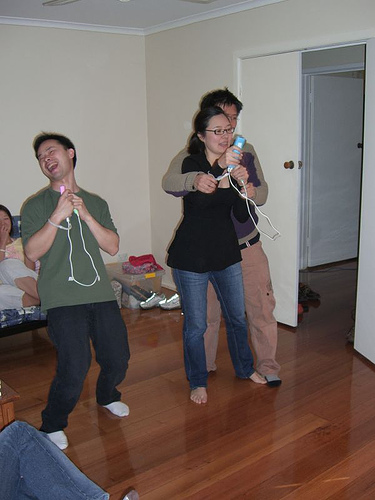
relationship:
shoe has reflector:
[157, 286, 180, 313] [154, 290, 175, 307]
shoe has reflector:
[135, 288, 169, 311] [134, 288, 157, 309]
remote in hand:
[229, 136, 247, 172] [215, 143, 241, 173]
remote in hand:
[229, 136, 247, 172] [230, 163, 250, 185]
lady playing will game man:
[164, 104, 269, 405] [162, 87, 268, 386]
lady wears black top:
[164, 104, 269, 405] [164, 148, 252, 274]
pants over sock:
[38, 300, 130, 433] [101, 401, 129, 417]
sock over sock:
[123, 489, 139, 499] [46, 430, 67, 448]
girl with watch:
[0, 197, 13, 331] [0, 245, 8, 254]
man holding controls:
[19, 133, 131, 449] [217, 129, 247, 179]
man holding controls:
[19, 133, 131, 449] [56, 179, 79, 224]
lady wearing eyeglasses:
[164, 104, 269, 405] [199, 127, 236, 138]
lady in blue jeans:
[164, 104, 269, 405] [168, 261, 261, 386]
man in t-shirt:
[19, 133, 131, 449] [20, 187, 117, 311]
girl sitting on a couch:
[0, 197, 41, 313] [1, 212, 55, 342]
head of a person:
[27, 126, 80, 179] [27, 131, 162, 365]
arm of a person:
[23, 188, 72, 269] [15, 126, 144, 451]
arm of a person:
[19, 188, 73, 265] [15, 126, 144, 451]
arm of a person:
[19, 188, 73, 265] [7, 123, 157, 390]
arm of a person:
[67, 192, 127, 260] [4, 123, 139, 457]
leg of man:
[37, 305, 90, 432] [19, 133, 131, 449]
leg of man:
[83, 301, 132, 408] [19, 133, 131, 449]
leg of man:
[173, 263, 208, 389] [19, 133, 131, 449]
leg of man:
[214, 262, 253, 377] [19, 133, 131, 449]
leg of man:
[237, 238, 292, 374] [19, 133, 131, 449]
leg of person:
[83, 301, 132, 408] [15, 126, 144, 451]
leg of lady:
[214, 262, 253, 377] [164, 104, 269, 405]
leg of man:
[237, 238, 292, 374] [161, 87, 282, 390]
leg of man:
[202, 276, 218, 372] [161, 87, 282, 390]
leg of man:
[83, 301, 132, 418] [161, 87, 282, 390]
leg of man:
[37, 305, 90, 432] [161, 87, 282, 390]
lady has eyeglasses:
[164, 104, 269, 405] [199, 127, 236, 138]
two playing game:
[158, 92, 297, 412] [215, 132, 293, 247]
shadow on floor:
[83, 401, 153, 499] [1, 252, 373, 489]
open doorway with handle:
[295, 39, 373, 170] [281, 156, 308, 172]